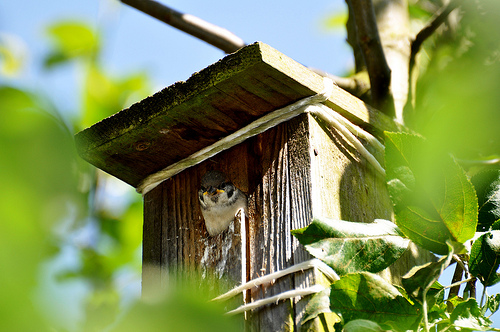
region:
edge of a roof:
[202, 74, 237, 82]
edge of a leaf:
[383, 196, 413, 221]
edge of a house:
[278, 134, 328, 186]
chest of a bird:
[204, 195, 227, 220]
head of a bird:
[186, 155, 230, 210]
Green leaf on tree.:
[399, 146, 474, 274]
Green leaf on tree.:
[333, 213, 407, 289]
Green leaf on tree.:
[336, 280, 378, 318]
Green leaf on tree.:
[440, 82, 499, 134]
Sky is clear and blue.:
[230, 19, 315, 24]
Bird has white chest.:
[212, 207, 248, 230]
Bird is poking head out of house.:
[182, 170, 282, 230]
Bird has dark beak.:
[210, 189, 225, 205]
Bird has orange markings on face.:
[203, 184, 226, 201]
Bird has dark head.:
[202, 165, 235, 187]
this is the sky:
[266, 5, 313, 39]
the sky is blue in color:
[273, 8, 311, 33]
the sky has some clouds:
[254, 5, 307, 33]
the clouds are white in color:
[305, 40, 340, 57]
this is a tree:
[290, 27, 498, 314]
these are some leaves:
[379, 107, 474, 259]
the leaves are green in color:
[389, 137, 473, 184]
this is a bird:
[183, 174, 248, 223]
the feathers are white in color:
[208, 205, 228, 230]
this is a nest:
[148, 202, 174, 242]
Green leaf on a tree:
[383, 125, 479, 260]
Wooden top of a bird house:
[47, 42, 332, 142]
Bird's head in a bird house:
[193, 172, 253, 237]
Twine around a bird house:
[126, 93, 389, 182]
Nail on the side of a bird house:
[311, 145, 321, 156]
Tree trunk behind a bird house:
[348, 0, 428, 122]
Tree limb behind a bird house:
[133, 1, 373, 100]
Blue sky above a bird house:
[1, 2, 364, 88]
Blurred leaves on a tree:
[4, 82, 136, 329]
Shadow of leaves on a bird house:
[343, 160, 408, 237]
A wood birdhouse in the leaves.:
[72, 41, 414, 331]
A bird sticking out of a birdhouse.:
[197, 169, 254, 240]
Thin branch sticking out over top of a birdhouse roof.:
[119, 0, 360, 92]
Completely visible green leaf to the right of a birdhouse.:
[379, 126, 477, 254]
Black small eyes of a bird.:
[197, 182, 227, 190]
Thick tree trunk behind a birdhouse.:
[343, 0, 418, 127]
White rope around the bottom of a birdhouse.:
[205, 251, 345, 311]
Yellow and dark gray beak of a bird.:
[196, 185, 226, 200]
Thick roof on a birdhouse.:
[68, 38, 425, 185]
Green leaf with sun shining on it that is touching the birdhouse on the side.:
[289, 217, 411, 272]